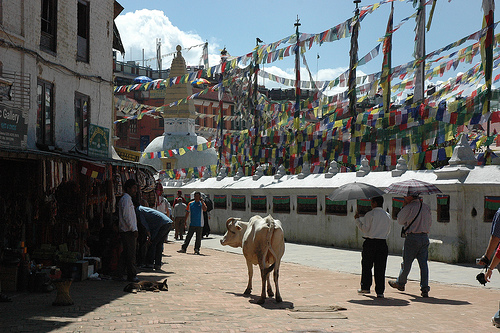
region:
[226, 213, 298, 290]
a white bull is in the street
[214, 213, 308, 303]
a white bull is looking at the people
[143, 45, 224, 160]
a statue in the background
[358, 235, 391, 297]
the man is wearing black pants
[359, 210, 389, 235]
the man is wearing a white shirt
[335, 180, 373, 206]
man is carrying a grey umbrella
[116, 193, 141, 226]
man in white shirt staring at the bull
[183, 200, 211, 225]
man in blue shirt is looking at the bull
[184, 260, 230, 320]
it is a reddish street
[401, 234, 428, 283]
man wearing blue jeans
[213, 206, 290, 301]
this is a cow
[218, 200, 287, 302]
the cow is white in color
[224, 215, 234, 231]
the horn is curved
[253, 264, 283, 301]
these are the rare legs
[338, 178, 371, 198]
this is an umbrella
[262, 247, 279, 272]
this is the tail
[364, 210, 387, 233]
the t shirt is white in color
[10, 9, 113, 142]
this is a building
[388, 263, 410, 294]
the leg is in front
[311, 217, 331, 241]
the wall is low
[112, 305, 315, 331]
The ground is made of concrete bricks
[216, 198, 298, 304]
A cow standing on the ground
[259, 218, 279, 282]
The tail of the cow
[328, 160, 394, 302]
The man walking with an umbrella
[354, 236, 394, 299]
The man is wearing black pants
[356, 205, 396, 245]
The man is wearing a white shirt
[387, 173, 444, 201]
The umbrella is plaid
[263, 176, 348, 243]
The building is the color white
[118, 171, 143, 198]
The head of the man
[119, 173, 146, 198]
The man has black hair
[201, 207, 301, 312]
Animal in middle of road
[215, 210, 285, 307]
animal looking to his left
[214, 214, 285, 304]
animal is white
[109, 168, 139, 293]
man looking at animal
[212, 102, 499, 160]
multi colored flags hung up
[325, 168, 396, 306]
man carring umbrella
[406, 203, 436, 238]
strap over shoulder of person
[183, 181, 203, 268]
person in blue and white shirt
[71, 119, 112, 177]
sign on the building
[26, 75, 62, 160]
window on top is closed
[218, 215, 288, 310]
a white cow in the street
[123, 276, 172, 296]
a dog laying down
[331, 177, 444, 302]
a pair of men with umbrellas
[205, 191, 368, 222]
a row of colorful curtains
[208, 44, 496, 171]
strings of colorful flags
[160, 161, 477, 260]
a long white building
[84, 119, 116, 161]
a square green sign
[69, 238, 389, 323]
a brick path way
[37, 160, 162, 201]
a display of products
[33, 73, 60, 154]
a window with a brown frame